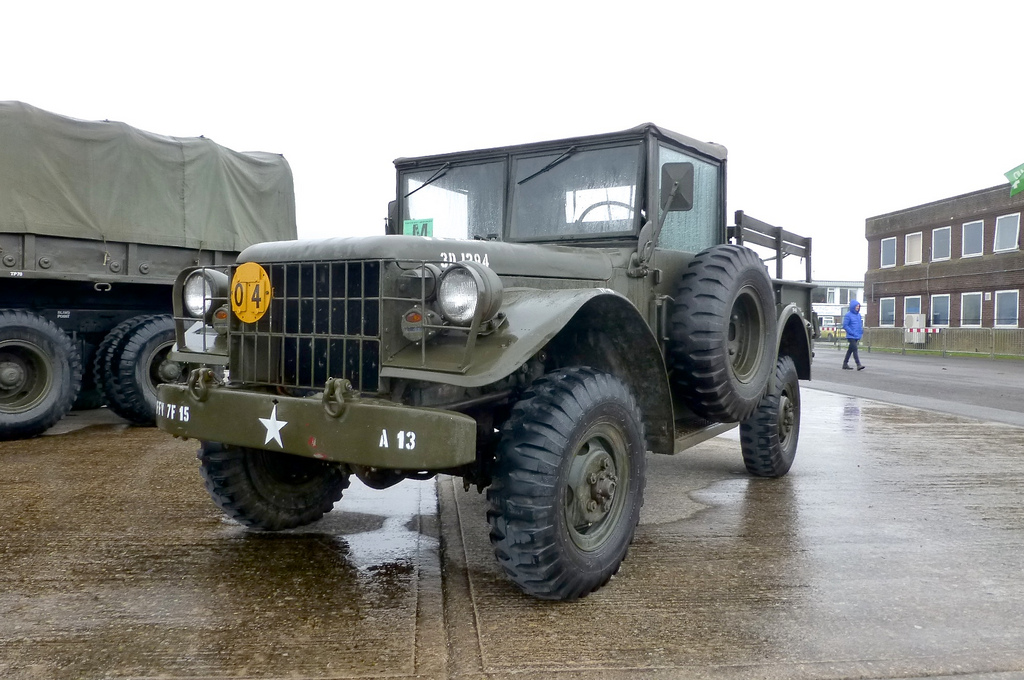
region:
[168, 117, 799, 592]
olive green army jeep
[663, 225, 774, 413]
black tire on the door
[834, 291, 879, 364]
person wearing blue jacket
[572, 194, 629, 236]
steering wheel in the jeep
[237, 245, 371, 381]
front grill on the jeep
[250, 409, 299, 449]
white star painted on the bumper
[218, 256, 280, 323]
yellow cirlce attached to the grill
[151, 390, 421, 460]
white numbers and letters painted on the bumper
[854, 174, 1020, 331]
brick building with white framed windows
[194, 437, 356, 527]
the large rubber wheel of the jeep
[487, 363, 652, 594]
the large rubber wheel of the jeep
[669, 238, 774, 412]
the large rubber wheel of the jeep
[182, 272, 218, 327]
the round headlight of the jeep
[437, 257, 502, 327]
the round headlight of the jeep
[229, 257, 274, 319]
the yellow circle sign of the jeep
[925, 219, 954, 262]
the square window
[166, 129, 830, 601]
The military jeep that is in full view.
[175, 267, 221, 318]
The left headlight of the military jeep.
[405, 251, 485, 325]
The right headlight of the military jeep.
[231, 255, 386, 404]
The front grill of the military jeep.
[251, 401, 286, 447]
The star on the fender of the military jeep.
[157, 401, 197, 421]
The number in the left corner of the fender of the military jeep.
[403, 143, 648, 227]
The windshield of the military jeep that is in full view.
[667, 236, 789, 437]
spare tire on side of jeep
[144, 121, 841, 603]
military issue green jeep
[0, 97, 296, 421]
green covered truck bed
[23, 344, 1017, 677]
wet cement parking area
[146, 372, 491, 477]
green bumper with white markings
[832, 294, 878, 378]
walking person in blue raincoat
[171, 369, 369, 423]
tow hooks on front bumper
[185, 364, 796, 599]
tires designed for rough terrain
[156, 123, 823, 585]
vehicle sitting with no driver in it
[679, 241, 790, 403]
A wheel on the jeep door.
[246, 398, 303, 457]
white star on bumper of jeep.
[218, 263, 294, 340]
yellow circle on the frame of jeep.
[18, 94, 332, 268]
green cover on back of truck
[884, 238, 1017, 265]
windows on the building.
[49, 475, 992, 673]
The ground is wet.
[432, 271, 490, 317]
Head light on the jeep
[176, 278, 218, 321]
Head light on the jeep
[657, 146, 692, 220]
mirror on the jeep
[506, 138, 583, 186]
windshield wiper on the jeep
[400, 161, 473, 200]
windshield wiper on the jeep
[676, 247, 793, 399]
black tire on the door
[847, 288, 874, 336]
person wearing a blue jacket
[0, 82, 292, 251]
green tarp on the truck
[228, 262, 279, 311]
yellow sign on the truck grill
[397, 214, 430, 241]
green sign on the window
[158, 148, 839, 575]
A army jeep on the road.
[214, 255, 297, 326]
A yellow circle in front of the jeep.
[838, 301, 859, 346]
The person is wearing a blue hoodie.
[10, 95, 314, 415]
A green army truck parked.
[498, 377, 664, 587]
The wheel is big.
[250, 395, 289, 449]
A white star in front of the jeep.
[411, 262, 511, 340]
The headlight on the jeep.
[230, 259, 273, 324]
round sign on a truck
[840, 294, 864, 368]
person in a blue rain coat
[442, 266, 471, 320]
round front headlight on a truck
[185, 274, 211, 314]
round front headlight on a truck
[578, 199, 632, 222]
large thin steering wheel visible through a windshield